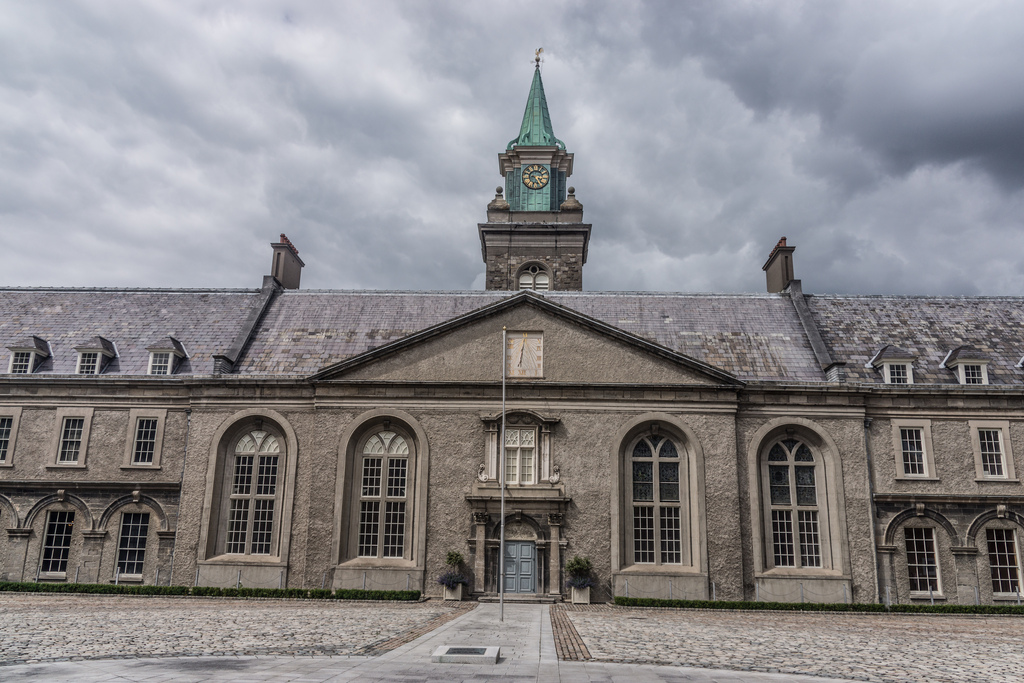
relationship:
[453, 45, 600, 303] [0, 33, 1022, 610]
steeple on top of building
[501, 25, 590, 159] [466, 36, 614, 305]
top on steeple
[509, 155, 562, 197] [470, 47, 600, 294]
clock on steeple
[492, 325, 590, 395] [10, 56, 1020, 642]
clock on front of building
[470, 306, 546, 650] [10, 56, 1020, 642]
pole in front of building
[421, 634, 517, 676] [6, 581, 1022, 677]
drain on sidewalk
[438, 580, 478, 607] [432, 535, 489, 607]
pot with plant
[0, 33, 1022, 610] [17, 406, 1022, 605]
building with windows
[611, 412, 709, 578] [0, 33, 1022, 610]
window on building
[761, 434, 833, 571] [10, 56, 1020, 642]
window on building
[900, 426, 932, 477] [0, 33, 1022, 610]
window on building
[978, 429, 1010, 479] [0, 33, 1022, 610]
window on building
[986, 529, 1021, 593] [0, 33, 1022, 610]
window on building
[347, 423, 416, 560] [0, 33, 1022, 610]
window on building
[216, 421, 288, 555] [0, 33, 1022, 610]
window on building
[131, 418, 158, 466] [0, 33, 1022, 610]
window on building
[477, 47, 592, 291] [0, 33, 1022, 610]
steeple on building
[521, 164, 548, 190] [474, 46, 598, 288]
clock on tower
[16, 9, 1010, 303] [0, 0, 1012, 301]
clouds in sky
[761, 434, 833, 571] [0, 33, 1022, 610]
window on building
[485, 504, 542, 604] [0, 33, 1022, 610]
door on building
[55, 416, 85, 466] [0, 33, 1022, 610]
window on building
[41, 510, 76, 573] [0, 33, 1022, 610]
window on building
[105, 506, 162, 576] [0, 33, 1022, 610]
window on building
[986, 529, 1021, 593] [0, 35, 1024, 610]
window on church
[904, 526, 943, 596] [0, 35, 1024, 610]
window on church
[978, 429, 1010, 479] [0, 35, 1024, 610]
window on church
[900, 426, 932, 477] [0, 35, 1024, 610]
window on church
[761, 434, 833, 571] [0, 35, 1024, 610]
window on church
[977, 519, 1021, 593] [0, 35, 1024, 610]
window on church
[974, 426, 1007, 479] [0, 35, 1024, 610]
window on church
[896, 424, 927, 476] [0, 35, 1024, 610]
window on church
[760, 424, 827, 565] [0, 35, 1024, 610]
window on church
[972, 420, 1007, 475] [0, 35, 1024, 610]
window on church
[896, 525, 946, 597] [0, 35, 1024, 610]
window on church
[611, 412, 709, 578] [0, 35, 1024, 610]
window on church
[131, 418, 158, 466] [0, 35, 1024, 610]
window on church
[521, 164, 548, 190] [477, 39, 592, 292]
clock on tower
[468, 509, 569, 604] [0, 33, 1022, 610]
door on building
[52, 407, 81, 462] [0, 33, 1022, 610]
window on building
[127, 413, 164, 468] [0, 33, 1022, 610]
window on building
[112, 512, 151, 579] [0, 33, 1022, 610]
window on building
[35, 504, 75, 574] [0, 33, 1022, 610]
window on building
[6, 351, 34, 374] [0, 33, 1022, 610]
window on building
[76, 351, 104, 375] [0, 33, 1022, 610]
window on building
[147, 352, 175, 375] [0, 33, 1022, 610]
window on building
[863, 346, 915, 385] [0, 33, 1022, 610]
window on building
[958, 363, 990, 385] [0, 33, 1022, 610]
window on building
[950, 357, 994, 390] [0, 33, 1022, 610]
window on building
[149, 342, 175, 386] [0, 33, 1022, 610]
window on building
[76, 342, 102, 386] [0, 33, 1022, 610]
window on building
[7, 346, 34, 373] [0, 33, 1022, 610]
window on building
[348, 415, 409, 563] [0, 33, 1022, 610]
window on building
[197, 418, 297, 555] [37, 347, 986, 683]
window in stone building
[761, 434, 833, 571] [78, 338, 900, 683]
window in stone building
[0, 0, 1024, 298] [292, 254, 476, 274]
clouds in sky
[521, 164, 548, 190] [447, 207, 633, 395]
clock on a tower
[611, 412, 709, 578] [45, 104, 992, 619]
window on church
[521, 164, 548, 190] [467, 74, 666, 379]
clock with steeple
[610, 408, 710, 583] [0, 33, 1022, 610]
window on building